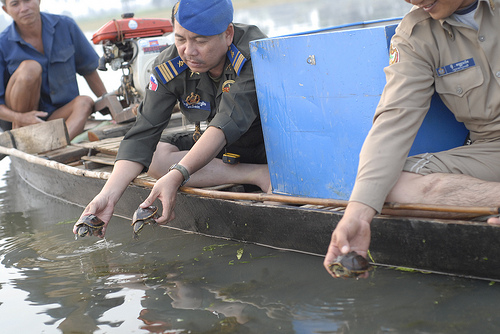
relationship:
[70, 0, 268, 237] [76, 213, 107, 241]
man has turtle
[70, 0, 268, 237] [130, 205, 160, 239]
man has turtle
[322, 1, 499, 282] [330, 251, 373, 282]
men holding turtle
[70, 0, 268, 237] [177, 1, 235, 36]
man wearing beret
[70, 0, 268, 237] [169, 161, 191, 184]
man wearing watch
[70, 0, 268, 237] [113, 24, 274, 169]
man wearing uniform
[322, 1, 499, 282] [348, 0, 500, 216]
men wearing uniform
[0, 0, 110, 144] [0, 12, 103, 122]
man wearing shirt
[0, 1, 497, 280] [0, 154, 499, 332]
men putting turtles in water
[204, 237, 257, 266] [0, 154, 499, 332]
vegetation in water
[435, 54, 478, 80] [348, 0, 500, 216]
id on military uniform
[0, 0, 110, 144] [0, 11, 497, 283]
man driving boat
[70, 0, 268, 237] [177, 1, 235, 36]
soldier in hat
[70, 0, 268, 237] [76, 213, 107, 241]
soldier releasing turtle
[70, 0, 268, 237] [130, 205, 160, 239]
soldier releasing turtle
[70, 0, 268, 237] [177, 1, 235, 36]
mat with hat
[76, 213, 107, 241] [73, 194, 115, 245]
turtle in man's hand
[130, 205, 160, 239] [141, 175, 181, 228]
turtle in man's hand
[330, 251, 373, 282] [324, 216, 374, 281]
turtle in man's hand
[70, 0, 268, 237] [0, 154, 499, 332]
person reaching into water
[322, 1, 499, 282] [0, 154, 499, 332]
men reaching into water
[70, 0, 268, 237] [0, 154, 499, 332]
person looking down at water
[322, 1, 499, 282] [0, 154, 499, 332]
men looking down at water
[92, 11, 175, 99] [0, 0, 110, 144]
engine next to man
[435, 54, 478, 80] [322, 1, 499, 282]
name tag on men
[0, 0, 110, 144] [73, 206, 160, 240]
man looking at turtles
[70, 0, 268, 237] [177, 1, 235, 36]
man wearing hat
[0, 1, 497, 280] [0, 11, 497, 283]
three men on boat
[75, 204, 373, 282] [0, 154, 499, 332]
turtles going in water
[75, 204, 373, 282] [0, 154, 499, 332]
turtles are ready to get in water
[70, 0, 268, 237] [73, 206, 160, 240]
man holding two turtles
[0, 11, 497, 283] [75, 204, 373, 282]
boat with turtles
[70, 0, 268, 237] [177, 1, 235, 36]
man with hat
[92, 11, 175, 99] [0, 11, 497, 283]
engine for boat